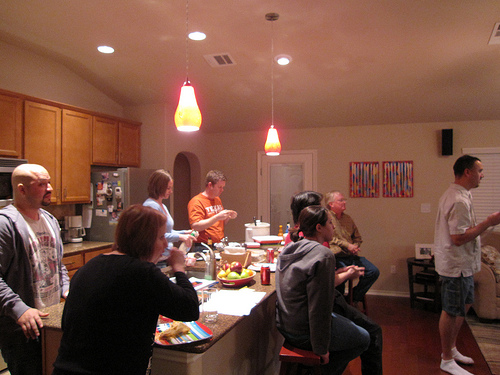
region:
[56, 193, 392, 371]
people are sitting at a kitchen island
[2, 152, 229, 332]
people are standing at the kitchen island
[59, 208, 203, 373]
the girl is eating at the counter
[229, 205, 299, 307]
beverages are on the counter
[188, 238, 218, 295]
the faucet at the kitchen sink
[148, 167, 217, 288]
the lady is turning the faucet off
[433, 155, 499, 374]
the man is standing with socks on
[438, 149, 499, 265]
the man is playing a game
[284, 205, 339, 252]
the girl has her hair in a ponytail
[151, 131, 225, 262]
an archway is in the kitchen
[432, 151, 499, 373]
man standing on wooden floor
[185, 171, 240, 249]
man wearing orange shirt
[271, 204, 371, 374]
girl with ponytail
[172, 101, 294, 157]
two lamps hanging from ceiling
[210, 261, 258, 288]
red plate with fruit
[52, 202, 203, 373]
woman drinking a glass of water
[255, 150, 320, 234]
wooden and glass door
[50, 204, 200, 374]
woman wearing black shirt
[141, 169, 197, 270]
girl with short hair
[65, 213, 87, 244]
coffee maker on kitchen counter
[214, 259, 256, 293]
bowl with red and yellow apples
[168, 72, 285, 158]
lights hanging from ceiling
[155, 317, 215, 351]
colorful plate on kitchen island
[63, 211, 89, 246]
coffee maker on countertop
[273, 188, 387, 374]
people watching a person playing a game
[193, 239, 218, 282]
sink faucet built in island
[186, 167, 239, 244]
man in orange is eating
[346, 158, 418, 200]
framed decoration on wall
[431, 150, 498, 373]
man playing in socks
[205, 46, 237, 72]
air vent in ceiling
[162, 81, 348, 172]
Lights above the crowd.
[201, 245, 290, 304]
Apples on the counter.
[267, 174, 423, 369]
Woman sitting down.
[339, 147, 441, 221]
Pictures on the kitchen wall.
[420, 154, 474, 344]
Man in a white shirt.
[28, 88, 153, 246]
Cabinets on the wall.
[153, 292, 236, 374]
Plate on the counter.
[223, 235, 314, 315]
Cokes on the counter.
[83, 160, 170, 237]
Fridge in the background.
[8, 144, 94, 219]
Man who is bald.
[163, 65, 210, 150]
a light hanging from a ceiling.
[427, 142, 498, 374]
a man standing in a kitchen.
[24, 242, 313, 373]
a bar in a kitchen.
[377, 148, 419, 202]
a poster on a wall.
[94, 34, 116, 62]
light in a ceiling.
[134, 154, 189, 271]
a woman standing in a kitchen.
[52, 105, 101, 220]
a wooden kitchen cabinet.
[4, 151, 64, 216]
a bald human head.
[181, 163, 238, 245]
a man in an orange shirt.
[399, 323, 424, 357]
a section of a wood floor.